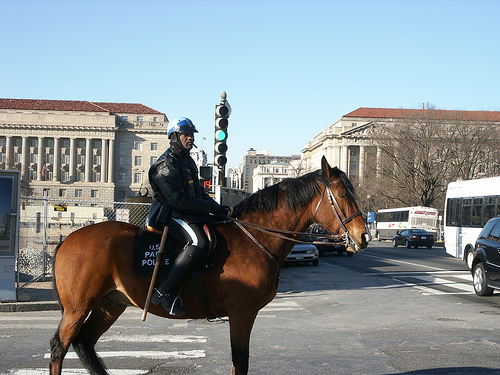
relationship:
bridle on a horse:
[313, 177, 368, 254] [45, 152, 371, 372]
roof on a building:
[339, 103, 499, 120] [303, 104, 497, 234]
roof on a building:
[0, 99, 169, 114] [303, 104, 497, 234]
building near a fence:
[303, 104, 497, 234] [0, 188, 153, 303]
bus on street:
[445, 175, 499, 263] [0, 238, 497, 371]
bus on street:
[372, 202, 442, 245] [0, 238, 497, 371]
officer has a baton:
[142, 107, 225, 320] [140, 225, 171, 322]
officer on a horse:
[142, 107, 225, 320] [45, 152, 371, 372]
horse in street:
[45, 152, 371, 372] [0, 238, 497, 371]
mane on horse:
[229, 170, 327, 218] [45, 152, 371, 372]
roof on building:
[339, 103, 499, 120] [303, 104, 497, 234]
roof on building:
[2, 96, 162, 114] [0, 98, 171, 278]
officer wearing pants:
[142, 107, 225, 320] [154, 205, 215, 316]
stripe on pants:
[171, 213, 200, 247] [154, 205, 215, 316]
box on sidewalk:
[1, 167, 22, 308] [0, 286, 61, 310]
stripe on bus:
[414, 208, 441, 215] [369, 201, 439, 241]